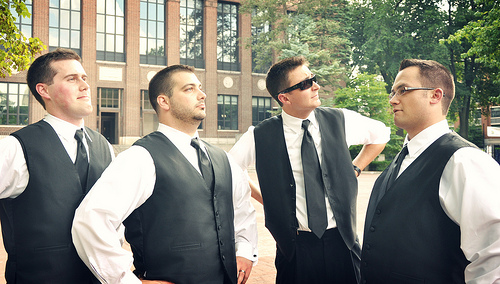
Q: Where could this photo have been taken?
A: In city park.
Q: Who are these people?
A: Men.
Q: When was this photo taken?
A: Daytime.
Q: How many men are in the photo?
A: Four.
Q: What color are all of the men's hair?
A: Brown.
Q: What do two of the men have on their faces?
A: Glasses.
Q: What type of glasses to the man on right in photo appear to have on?
A: Eyeglasses.